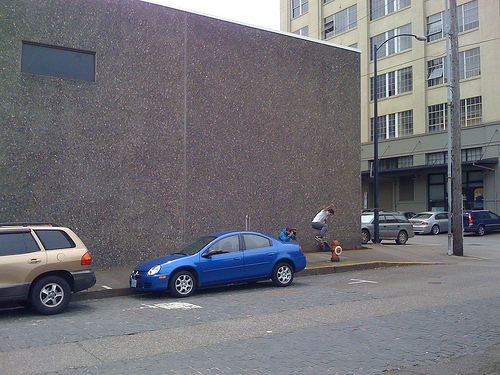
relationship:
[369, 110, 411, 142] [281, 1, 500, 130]
window on building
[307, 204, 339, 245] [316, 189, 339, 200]
person in air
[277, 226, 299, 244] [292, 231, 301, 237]
cameraman taking photograph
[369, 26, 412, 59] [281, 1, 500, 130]
window on building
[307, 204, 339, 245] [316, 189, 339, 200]
skateboarder in air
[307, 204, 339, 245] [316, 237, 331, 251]
man on skateboard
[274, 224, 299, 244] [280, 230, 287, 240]
cameraman wearing blue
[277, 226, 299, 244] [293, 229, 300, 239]
cameraman holding camera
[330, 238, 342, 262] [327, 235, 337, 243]
hydrant in front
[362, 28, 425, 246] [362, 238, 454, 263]
lamppost on corner